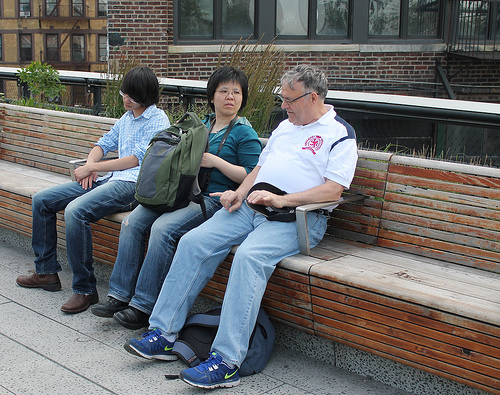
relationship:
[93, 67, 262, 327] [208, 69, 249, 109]
woman has dark hair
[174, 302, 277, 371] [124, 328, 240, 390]
bag behind shoes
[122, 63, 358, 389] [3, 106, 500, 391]
man on bench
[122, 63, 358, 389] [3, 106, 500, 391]
man sitting on bench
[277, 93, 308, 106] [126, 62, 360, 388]
glasses on a man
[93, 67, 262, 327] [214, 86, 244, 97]
woman wears glasses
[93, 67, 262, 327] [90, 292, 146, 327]
woman wears shoes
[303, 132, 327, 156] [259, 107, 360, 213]
emblem on shirt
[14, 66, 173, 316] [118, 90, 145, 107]
boy wears glasses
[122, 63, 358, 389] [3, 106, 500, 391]
man on a bench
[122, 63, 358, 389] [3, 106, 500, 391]
man sit on a bench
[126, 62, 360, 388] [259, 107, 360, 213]
man wears white shirt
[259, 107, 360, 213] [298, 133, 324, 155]
shirt has a red emblem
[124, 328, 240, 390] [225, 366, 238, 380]
shoes have a green check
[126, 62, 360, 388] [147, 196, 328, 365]
man wears jeans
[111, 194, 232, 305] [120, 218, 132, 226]
jeans with a tear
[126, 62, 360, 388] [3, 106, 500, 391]
man sits on a bench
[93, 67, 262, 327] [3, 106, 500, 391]
woman sits on a bench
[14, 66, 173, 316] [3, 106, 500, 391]
boy sits on a bench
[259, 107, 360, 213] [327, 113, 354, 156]
shirt has blue trim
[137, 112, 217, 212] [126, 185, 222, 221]
backpack on a lap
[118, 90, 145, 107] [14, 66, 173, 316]
glasses on boy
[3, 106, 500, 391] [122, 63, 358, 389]
bench seating man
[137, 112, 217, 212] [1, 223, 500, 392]
backpack on sidewalk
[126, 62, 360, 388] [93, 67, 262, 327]
man sitting by woman